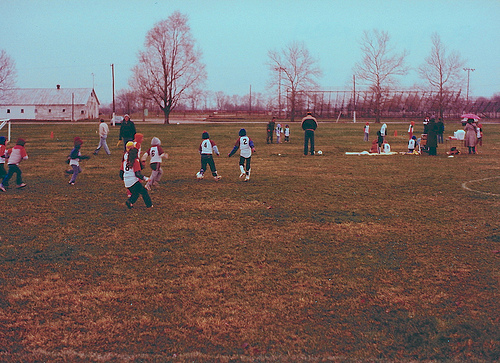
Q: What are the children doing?
A: Playing soccer.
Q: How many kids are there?
A: At least 15.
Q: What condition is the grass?
A: Dormant.